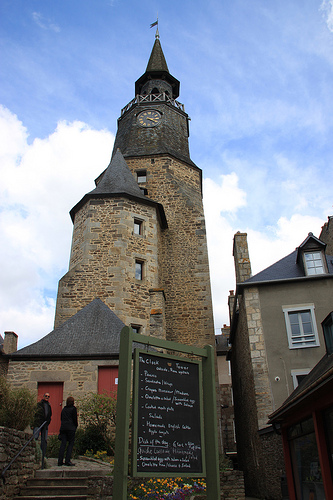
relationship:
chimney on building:
[228, 228, 254, 279] [213, 214, 331, 498]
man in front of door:
[31, 387, 51, 467] [34, 380, 64, 435]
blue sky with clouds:
[37, 22, 132, 65] [9, 115, 85, 181]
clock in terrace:
[137, 110, 162, 126] [114, 94, 185, 116]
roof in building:
[144, 38, 172, 70] [0, 91, 213, 498]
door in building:
[36, 382, 62, 433] [0, 91, 213, 498]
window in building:
[132, 217, 143, 236] [0, 91, 213, 498]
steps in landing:
[14, 465, 87, 498] [35, 453, 111, 475]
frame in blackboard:
[132, 347, 205, 481] [139, 354, 199, 471]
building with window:
[224, 223, 332, 497] [282, 304, 321, 349]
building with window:
[0, 12, 333, 499] [287, 419, 326, 497]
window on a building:
[281, 296, 321, 352] [224, 223, 332, 497]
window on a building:
[303, 250, 325, 274] [224, 223, 332, 497]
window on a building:
[130, 321, 142, 334] [0, 17, 216, 456]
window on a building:
[134, 259, 148, 283] [60, 149, 171, 333]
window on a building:
[134, 217, 143, 237] [55, 149, 165, 337]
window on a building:
[132, 217, 143, 236] [100, 60, 219, 321]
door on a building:
[36, 382, 63, 438] [2, 14, 222, 495]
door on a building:
[96, 363, 118, 408] [5, 294, 159, 456]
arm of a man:
[36, 406, 44, 427] [32, 392, 51, 456]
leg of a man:
[38, 431, 46, 462] [23, 381, 62, 456]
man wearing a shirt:
[56, 397, 79, 463] [35, 400, 52, 424]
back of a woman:
[59, 406, 80, 435] [54, 395, 82, 466]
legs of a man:
[57, 439, 76, 466] [56, 397, 78, 467]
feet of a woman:
[58, 453, 81, 470] [41, 354, 114, 468]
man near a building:
[56, 397, 78, 467] [2, 14, 222, 495]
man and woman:
[33, 391, 52, 466] [59, 394, 80, 463]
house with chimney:
[238, 234, 321, 362] [232, 231, 251, 279]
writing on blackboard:
[141, 363, 196, 467] [139, 354, 202, 474]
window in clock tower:
[132, 217, 143, 236] [50, 18, 224, 459]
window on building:
[278, 304, 324, 351] [232, 260, 321, 435]